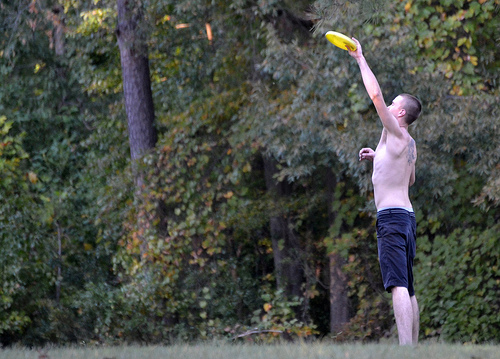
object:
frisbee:
[324, 30, 357, 52]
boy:
[342, 36, 420, 345]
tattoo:
[397, 138, 420, 167]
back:
[391, 128, 415, 209]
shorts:
[375, 207, 417, 296]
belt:
[373, 208, 422, 221]